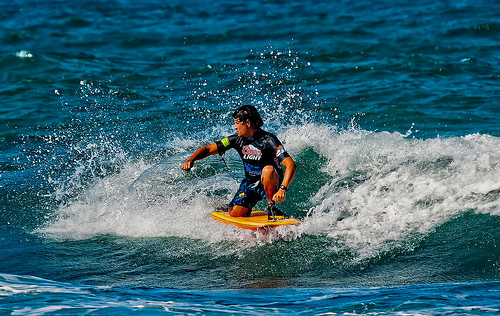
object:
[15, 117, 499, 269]
wave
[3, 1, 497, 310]
sea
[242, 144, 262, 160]
coors light logo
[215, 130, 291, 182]
shirt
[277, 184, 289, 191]
watch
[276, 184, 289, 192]
wrist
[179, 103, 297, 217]
surfer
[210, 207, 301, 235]
surfboard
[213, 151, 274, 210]
surfer leash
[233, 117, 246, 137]
face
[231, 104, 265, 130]
hair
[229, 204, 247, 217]
knee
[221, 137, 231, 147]
pad